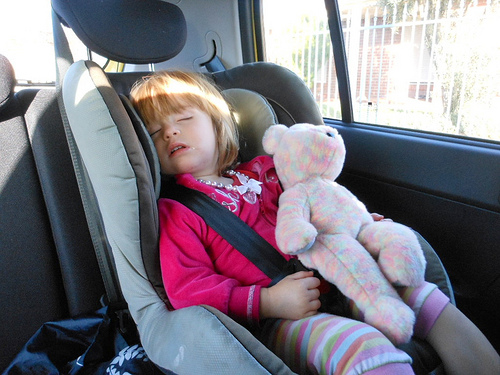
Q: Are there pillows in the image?
A: No, there are no pillows.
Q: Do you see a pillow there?
A: No, there are no pillows.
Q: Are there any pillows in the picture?
A: No, there are no pillows.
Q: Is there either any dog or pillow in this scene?
A: No, there are no pillows or dogs.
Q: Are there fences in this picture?
A: Yes, there is a fence.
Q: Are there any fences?
A: Yes, there is a fence.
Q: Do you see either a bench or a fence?
A: Yes, there is a fence.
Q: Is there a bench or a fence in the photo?
A: Yes, there is a fence.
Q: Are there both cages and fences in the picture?
A: No, there is a fence but no cages.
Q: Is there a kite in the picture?
A: No, there are no kites.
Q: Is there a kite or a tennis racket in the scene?
A: No, there are no kites or rackets.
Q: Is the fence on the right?
A: Yes, the fence is on the right of the image.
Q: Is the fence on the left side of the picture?
A: No, the fence is on the right of the image.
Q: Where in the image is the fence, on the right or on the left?
A: The fence is on the right of the image.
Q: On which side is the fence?
A: The fence is on the right of the image.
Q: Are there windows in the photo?
A: Yes, there is a window.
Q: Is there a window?
A: Yes, there is a window.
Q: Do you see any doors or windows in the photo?
A: Yes, there is a window.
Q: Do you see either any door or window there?
A: Yes, there is a window.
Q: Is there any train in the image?
A: No, there are no trains.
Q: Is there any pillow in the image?
A: No, there are no pillows.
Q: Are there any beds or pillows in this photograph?
A: No, there are no pillows or beds.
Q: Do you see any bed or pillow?
A: No, there are no pillows or beds.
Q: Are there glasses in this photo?
A: No, there are no glasses.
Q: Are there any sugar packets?
A: No, there are no sugar packets.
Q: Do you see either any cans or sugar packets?
A: No, there are no sugar packets or cans.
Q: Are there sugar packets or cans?
A: No, there are no sugar packets or cans.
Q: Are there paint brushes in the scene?
A: No, there are no paint brushes.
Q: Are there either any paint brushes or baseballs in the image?
A: No, there are no paint brushes or baseballs.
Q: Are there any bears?
A: Yes, there is a bear.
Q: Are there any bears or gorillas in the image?
A: Yes, there is a bear.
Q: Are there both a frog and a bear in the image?
A: No, there is a bear but no frogs.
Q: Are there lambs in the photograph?
A: No, there are no lambs.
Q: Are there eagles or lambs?
A: No, there are no lambs or eagles.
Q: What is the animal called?
A: The animal is a bear.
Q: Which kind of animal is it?
A: The animal is a bear.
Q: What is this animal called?
A: This is a bear.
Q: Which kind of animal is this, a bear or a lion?
A: This is a bear.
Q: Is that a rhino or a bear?
A: That is a bear.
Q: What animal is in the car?
A: The animal is a bear.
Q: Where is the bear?
A: The bear is in the car.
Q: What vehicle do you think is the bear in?
A: The bear is in the car.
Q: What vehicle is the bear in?
A: The bear is in the car.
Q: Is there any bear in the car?
A: Yes, there is a bear in the car.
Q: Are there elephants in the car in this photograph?
A: No, there is a bear in the car.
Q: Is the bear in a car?
A: Yes, the bear is in a car.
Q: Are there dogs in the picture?
A: No, there are no dogs.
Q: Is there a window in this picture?
A: Yes, there is a window.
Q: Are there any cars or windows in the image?
A: Yes, there is a window.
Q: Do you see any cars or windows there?
A: Yes, there is a window.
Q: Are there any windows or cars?
A: Yes, there is a window.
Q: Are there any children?
A: Yes, there is a child.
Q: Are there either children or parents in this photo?
A: Yes, there is a child.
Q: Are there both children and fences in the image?
A: Yes, there are both a child and a fence.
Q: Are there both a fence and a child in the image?
A: Yes, there are both a child and a fence.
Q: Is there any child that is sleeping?
A: Yes, there is a child that is sleeping.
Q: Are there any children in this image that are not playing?
A: Yes, there is a child that is sleeping.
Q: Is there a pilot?
A: No, there are no pilots.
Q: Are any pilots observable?
A: No, there are no pilots.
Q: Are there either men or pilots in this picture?
A: No, there are no pilots or men.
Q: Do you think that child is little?
A: Yes, the child is little.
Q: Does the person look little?
A: Yes, the kid is little.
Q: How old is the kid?
A: The kid is little.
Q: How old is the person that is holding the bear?
A: The kid is little.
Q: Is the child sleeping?
A: Yes, the child is sleeping.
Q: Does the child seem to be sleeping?
A: Yes, the child is sleeping.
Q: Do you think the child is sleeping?
A: Yes, the child is sleeping.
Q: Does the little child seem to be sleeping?
A: Yes, the kid is sleeping.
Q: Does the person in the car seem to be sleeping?
A: Yes, the kid is sleeping.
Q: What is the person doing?
A: The child is sleeping.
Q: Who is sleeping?
A: The child is sleeping.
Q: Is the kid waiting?
A: No, the kid is sleeping.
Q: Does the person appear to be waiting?
A: No, the child is sleeping.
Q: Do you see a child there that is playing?
A: No, there is a child but he is sleeping.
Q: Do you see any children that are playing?
A: No, there is a child but he is sleeping.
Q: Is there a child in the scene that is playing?
A: No, there is a child but he is sleeping.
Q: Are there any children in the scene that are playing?
A: No, there is a child but he is sleeping.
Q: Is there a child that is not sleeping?
A: No, there is a child but he is sleeping.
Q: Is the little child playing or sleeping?
A: The child is sleeping.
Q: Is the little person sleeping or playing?
A: The child is sleeping.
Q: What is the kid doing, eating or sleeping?
A: The kid is sleeping.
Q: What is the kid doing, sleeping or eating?
A: The kid is sleeping.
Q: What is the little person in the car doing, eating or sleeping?
A: The kid is sleeping.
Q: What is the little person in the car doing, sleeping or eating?
A: The kid is sleeping.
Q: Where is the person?
A: The child is in the car.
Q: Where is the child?
A: The child is in the car.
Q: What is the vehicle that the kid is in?
A: The vehicle is a car.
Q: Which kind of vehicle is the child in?
A: The kid is in the car.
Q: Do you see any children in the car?
A: Yes, there is a child in the car.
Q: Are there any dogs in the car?
A: No, there is a child in the car.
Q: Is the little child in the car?
A: Yes, the kid is in the car.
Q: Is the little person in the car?
A: Yes, the kid is in the car.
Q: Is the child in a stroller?
A: No, the child is in the car.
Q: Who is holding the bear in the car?
A: The child is holding the bear.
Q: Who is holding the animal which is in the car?
A: The child is holding the bear.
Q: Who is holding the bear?
A: The child is holding the bear.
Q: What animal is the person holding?
A: The kid is holding the bear.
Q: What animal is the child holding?
A: The kid is holding the bear.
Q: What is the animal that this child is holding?
A: The animal is a bear.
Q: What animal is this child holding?
A: The child is holding the bear.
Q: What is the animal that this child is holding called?
A: The animal is a bear.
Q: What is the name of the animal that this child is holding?
A: The animal is a bear.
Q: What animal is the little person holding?
A: The child is holding the bear.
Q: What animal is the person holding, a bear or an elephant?
A: The child is holding a bear.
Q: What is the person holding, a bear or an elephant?
A: The child is holding a bear.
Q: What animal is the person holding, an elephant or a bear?
A: The child is holding a bear.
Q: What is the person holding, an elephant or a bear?
A: The child is holding a bear.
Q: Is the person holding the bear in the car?
A: Yes, the child is holding the bear.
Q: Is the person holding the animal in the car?
A: Yes, the child is holding the bear.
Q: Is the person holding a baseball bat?
A: No, the kid is holding the bear.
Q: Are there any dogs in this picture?
A: No, there are no dogs.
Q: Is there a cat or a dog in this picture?
A: No, there are no dogs or cats.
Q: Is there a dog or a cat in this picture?
A: No, there are no dogs or cats.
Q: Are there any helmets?
A: No, there are no helmets.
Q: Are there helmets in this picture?
A: No, there are no helmets.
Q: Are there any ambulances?
A: No, there are no ambulances.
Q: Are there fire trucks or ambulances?
A: No, there are no ambulances or fire trucks.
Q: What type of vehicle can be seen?
A: The vehicle is a car.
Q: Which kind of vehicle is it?
A: The vehicle is a car.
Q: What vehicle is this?
A: This is a car.